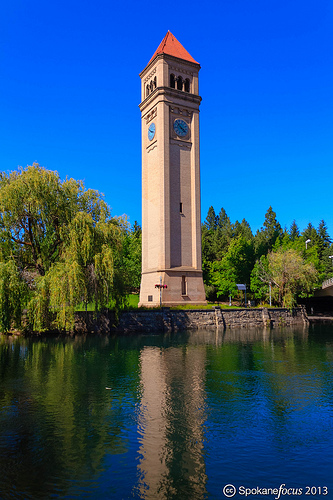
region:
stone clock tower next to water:
[136, 28, 208, 308]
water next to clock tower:
[2, 319, 332, 498]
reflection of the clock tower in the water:
[133, 339, 211, 498]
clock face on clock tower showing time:
[173, 117, 190, 136]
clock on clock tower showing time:
[147, 122, 155, 140]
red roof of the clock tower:
[136, 27, 203, 72]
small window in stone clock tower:
[178, 200, 183, 213]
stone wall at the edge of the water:
[24, 305, 310, 331]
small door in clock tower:
[181, 274, 188, 295]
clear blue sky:
[0, 1, 332, 235]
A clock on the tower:
[169, 112, 188, 140]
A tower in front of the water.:
[130, 54, 221, 290]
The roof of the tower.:
[151, 30, 190, 59]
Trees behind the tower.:
[28, 189, 274, 289]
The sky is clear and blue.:
[43, 84, 134, 155]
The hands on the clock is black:
[175, 120, 186, 132]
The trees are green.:
[24, 183, 121, 280]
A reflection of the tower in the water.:
[118, 366, 247, 458]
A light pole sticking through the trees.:
[298, 231, 317, 251]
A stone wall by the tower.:
[102, 306, 251, 326]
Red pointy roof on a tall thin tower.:
[147, 30, 198, 62]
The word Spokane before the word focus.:
[238, 484, 279, 495]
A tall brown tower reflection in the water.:
[136, 341, 207, 498]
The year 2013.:
[305, 486, 328, 495]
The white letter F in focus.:
[274, 482, 283, 499]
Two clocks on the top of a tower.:
[146, 119, 188, 140]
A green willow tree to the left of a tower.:
[25, 209, 114, 332]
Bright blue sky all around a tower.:
[0, 1, 332, 226]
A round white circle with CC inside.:
[223, 482, 236, 497]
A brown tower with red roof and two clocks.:
[137, 29, 207, 304]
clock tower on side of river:
[136, 19, 210, 319]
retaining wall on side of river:
[50, 299, 312, 338]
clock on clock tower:
[170, 113, 190, 137]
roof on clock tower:
[137, 26, 208, 64]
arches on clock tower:
[166, 70, 195, 94]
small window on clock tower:
[175, 196, 184, 221]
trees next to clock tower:
[4, 154, 121, 304]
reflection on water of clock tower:
[132, 325, 216, 499]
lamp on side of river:
[148, 271, 172, 305]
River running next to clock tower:
[12, 334, 328, 479]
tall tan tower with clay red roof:
[133, 26, 214, 307]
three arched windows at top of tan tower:
[163, 66, 195, 94]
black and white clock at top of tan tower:
[171, 110, 191, 142]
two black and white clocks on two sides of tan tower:
[142, 116, 193, 144]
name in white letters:
[237, 483, 304, 498]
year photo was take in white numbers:
[303, 483, 330, 496]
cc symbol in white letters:
[215, 481, 238, 498]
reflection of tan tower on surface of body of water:
[127, 331, 222, 498]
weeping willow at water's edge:
[0, 159, 127, 335]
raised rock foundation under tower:
[44, 306, 308, 335]